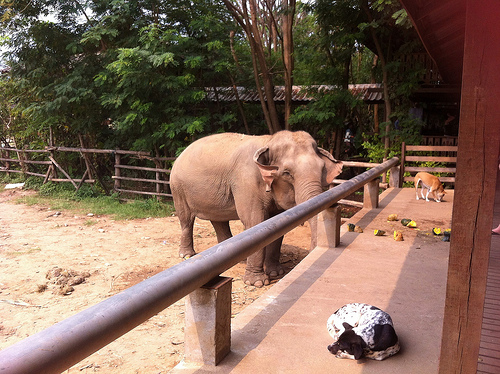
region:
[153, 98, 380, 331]
This is an elephant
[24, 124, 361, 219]
This is a wooden fence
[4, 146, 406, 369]
This is a metal fence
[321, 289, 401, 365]
This is a dog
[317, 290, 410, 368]
The dog is spotted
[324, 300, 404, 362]
The dog is sleeping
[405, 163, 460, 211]
This is a dog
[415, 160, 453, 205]
This dog is sniffing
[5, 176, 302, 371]
Large dirt patch in elephant area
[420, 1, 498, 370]
Long wooden pole on deck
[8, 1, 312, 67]
light of daytime sky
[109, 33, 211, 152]
green leaves of tree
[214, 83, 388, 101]
slanted metal roof under trees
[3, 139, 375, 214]
wood fence in front of trees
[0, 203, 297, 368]
dirt surface of enclosure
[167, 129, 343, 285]
elephant standing in front of deck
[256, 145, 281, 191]
flapping ear of elephant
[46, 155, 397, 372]
metal pole on deck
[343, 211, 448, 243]
fruit scattered on deck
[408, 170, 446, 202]
dog with head down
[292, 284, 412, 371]
a dog sleeping on walkway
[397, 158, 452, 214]
a brown and white dog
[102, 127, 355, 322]
a elephant in a pen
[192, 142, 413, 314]
a metal railing along a walkway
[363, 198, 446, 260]
pieces of fruit on a walkway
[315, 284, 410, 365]
a black and white dog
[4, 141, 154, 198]
a wood fence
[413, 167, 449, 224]
a dog sniffing the ground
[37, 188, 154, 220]
a patch of grass next to a fence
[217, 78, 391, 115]
a building with an tin roof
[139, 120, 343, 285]
an elephant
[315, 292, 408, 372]
a dog curled up on the porch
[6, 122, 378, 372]
an elephant in a pen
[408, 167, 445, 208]
a tan and white dog on the porch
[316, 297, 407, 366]
a black and white dog sleeps on the porch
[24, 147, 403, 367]
a metal railing on the deck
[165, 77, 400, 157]
a building in the trees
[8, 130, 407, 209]
a wooden fence along the pen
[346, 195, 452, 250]
food is on the deck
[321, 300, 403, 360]
small black and white dog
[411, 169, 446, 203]
small dog is brown and white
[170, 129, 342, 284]
the elephant is gray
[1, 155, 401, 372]
large metal pole on pillars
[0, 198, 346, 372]
brown dirt under elephant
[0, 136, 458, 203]
wood fence behind elephant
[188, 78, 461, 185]
a building behind trees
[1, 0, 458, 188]
large leafy green trees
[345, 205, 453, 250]
sliced fruit on deck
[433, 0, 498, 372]
large wooden pillars on patio